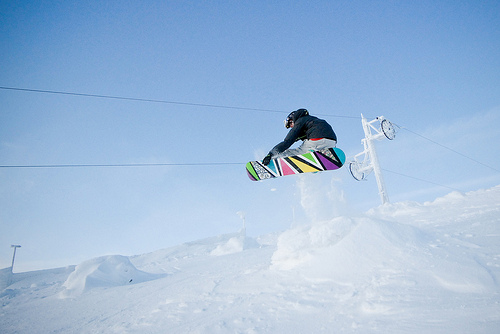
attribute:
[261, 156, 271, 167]
glove — black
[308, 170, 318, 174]
glove — black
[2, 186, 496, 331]
snow — blazing, white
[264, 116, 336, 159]
coat — black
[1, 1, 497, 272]
sky — beautiful, blue, clear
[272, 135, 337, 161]
pants — gray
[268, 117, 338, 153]
jacket — dark, blue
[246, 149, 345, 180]
board — colorful, snow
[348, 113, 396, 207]
apparatus — large, metal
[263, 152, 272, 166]
hand — man's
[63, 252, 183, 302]
drift — large, snow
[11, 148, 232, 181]
wire — metal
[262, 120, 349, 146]
coat — blue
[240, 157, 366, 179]
pants — pink, yellow, black, green, purple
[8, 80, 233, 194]
wires — black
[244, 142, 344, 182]
snowboard — Bottom 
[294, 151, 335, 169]
colors — many 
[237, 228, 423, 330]
snow — feet 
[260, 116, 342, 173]
jacket — black 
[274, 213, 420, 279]
snow — Pile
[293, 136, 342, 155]
pants — White snowboard 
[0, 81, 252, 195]
line — Cable 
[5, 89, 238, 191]
lifts — chair 